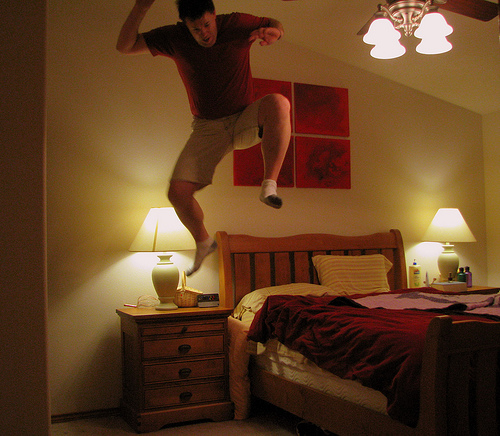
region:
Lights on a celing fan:
[348, 8, 486, 77]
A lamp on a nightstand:
[118, 200, 212, 323]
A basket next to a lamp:
[171, 263, 201, 317]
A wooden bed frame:
[209, 209, 438, 293]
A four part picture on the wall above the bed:
[219, 67, 361, 204]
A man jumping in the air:
[144, 8, 314, 209]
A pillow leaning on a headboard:
[305, 244, 405, 306]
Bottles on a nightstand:
[397, 261, 483, 289]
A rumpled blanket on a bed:
[241, 273, 368, 367]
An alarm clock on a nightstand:
[187, 285, 244, 317]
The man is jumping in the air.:
[107, 16, 315, 267]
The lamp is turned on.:
[130, 209, 217, 319]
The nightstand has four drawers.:
[121, 310, 249, 434]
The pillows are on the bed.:
[228, 252, 415, 337]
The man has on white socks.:
[241, 176, 285, 220]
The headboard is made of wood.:
[211, 226, 424, 291]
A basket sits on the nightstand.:
[166, 271, 202, 316]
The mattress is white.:
[248, 343, 388, 408]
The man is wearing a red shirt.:
[135, 25, 280, 125]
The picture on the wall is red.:
[239, 76, 364, 202]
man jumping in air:
[112, 7, 373, 410]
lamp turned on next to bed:
[109, 199, 326, 421]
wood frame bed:
[214, 209, 496, 376]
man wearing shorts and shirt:
[136, 16, 326, 246]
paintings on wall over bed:
[240, 59, 371, 342]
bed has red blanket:
[245, 220, 480, 415]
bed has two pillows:
[247, 237, 478, 310]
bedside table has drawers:
[121, 247, 282, 434]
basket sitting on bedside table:
[154, 270, 238, 400]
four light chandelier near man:
[175, 9, 498, 96]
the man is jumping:
[112, 1, 305, 280]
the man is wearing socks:
[180, 174, 289, 279]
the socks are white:
[173, 173, 292, 275]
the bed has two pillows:
[234, 247, 399, 329]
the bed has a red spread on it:
[249, 280, 498, 407]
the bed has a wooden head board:
[211, 216, 425, 346]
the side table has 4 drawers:
[138, 317, 230, 419]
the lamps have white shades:
[121, 203, 481, 262]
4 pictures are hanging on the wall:
[223, 71, 364, 204]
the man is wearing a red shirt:
[137, 5, 269, 119]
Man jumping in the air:
[102, 0, 304, 278]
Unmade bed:
[219, 228, 495, 433]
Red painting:
[237, 71, 357, 197]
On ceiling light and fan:
[336, 0, 498, 57]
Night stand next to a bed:
[119, 302, 239, 432]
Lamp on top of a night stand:
[114, 194, 228, 367]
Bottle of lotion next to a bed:
[406, 256, 424, 291]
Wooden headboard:
[214, 230, 417, 317]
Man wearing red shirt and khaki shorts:
[114, 0, 306, 280]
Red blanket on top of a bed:
[251, 273, 498, 410]